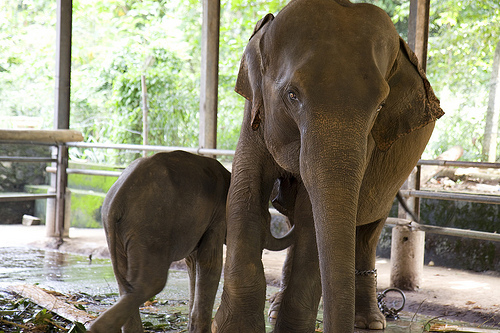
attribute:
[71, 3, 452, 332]
elephants — big, brown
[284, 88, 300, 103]
eye — small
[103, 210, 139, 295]
tail — long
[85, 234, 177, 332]
legs — large, brown, back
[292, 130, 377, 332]
trunk — long, large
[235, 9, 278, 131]
ear — large, floppy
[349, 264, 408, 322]
chain — grey, small, silver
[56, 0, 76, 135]
beam — tall, brown, wooden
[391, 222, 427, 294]
cement block — pictured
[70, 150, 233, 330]
elephant — smaller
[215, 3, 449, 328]
elephant — large, baby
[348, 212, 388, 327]
leg — back